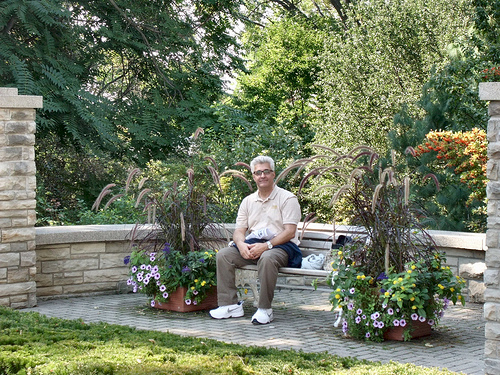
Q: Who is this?
A: Person.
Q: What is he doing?
A: Sitting.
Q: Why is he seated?
A: Relaxing.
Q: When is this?
A: Daytime.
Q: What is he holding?
A: Hands.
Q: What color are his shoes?
A: White.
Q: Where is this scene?
A: In a garden.